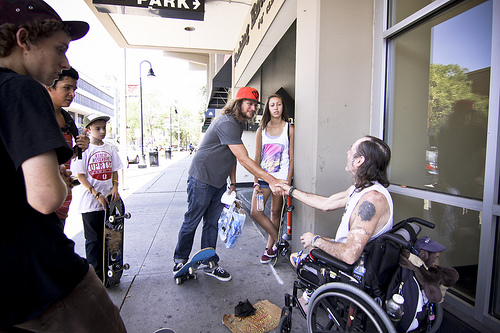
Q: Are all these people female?
A: No, they are both male and female.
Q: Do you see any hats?
A: Yes, there is a hat.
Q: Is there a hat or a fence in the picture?
A: Yes, there is a hat.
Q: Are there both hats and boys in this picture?
A: Yes, there are both a hat and a boy.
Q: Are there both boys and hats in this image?
A: Yes, there are both a hat and a boy.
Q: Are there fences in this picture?
A: No, there are no fences.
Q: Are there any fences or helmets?
A: No, there are no fences or helmets.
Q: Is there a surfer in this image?
A: No, there are no surfers.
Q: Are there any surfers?
A: No, there are no surfers.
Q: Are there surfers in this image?
A: No, there are no surfers.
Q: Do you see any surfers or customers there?
A: No, there are no surfers or customers.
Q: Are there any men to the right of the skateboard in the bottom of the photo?
A: Yes, there is a man to the right of the skateboard.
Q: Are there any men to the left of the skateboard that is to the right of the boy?
A: No, the man is to the right of the skateboard.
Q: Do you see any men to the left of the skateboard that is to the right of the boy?
A: No, the man is to the right of the skateboard.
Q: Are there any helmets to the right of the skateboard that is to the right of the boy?
A: No, there is a man to the right of the skateboard.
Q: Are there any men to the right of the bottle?
A: Yes, there is a man to the right of the bottle.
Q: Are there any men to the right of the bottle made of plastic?
A: Yes, there is a man to the right of the bottle.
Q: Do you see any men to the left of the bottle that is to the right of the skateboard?
A: No, the man is to the right of the bottle.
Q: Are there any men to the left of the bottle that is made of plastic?
A: No, the man is to the right of the bottle.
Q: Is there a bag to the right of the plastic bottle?
A: No, there is a man to the right of the bottle.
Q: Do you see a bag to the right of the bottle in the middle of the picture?
A: No, there is a man to the right of the bottle.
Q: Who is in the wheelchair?
A: The man is in the wheelchair.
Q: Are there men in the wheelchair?
A: Yes, there is a man in the wheelchair.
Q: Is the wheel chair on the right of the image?
A: Yes, the wheel chair is on the right of the image.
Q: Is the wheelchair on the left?
A: No, the wheelchair is on the right of the image.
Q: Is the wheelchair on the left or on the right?
A: The wheelchair is on the right of the image.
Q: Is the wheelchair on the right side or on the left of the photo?
A: The wheelchair is on the right of the image.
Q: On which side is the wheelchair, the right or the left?
A: The wheelchair is on the right of the image.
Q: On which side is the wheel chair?
A: The wheel chair is on the right of the image.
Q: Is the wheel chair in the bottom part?
A: Yes, the wheel chair is in the bottom of the image.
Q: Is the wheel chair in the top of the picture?
A: No, the wheel chair is in the bottom of the image.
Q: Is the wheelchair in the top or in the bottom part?
A: The wheelchair is in the bottom of the image.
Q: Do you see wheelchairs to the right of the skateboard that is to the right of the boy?
A: Yes, there is a wheelchair to the right of the skateboard.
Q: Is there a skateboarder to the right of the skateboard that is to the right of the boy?
A: No, there is a wheelchair to the right of the skateboard.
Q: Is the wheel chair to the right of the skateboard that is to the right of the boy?
A: Yes, the wheel chair is to the right of the skateboard.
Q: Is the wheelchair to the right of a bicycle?
A: No, the wheelchair is to the right of the skateboard.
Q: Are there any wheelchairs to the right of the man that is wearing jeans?
A: Yes, there is a wheelchair to the right of the man.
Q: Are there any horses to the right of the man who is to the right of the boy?
A: No, there is a wheelchair to the right of the man.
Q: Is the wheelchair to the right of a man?
A: Yes, the wheelchair is to the right of a man.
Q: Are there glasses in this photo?
A: No, there are no glasses.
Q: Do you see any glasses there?
A: No, there are no glasses.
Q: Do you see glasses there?
A: No, there are no glasses.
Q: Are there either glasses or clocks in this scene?
A: No, there are no glasses or clocks.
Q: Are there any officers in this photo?
A: No, there are no officers.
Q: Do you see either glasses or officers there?
A: No, there are no officers or glasses.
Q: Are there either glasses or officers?
A: No, there are no officers or glasses.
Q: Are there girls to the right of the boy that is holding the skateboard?
A: Yes, there is a girl to the right of the boy.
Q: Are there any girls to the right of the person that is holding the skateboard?
A: Yes, there is a girl to the right of the boy.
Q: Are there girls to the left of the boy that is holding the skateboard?
A: No, the girl is to the right of the boy.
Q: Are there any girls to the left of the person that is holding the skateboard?
A: No, the girl is to the right of the boy.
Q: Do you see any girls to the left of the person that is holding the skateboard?
A: No, the girl is to the right of the boy.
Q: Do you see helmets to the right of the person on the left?
A: No, there is a girl to the right of the boy.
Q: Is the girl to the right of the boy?
A: Yes, the girl is to the right of the boy.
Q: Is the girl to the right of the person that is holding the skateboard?
A: Yes, the girl is to the right of the boy.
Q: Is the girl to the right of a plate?
A: No, the girl is to the right of the boy.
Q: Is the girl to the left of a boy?
A: No, the girl is to the right of a boy.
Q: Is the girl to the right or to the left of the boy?
A: The girl is to the right of the boy.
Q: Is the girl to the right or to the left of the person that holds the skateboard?
A: The girl is to the right of the boy.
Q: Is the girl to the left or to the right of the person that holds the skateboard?
A: The girl is to the right of the boy.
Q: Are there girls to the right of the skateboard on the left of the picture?
A: Yes, there is a girl to the right of the skateboard.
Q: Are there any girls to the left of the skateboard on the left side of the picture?
A: No, the girl is to the right of the skateboard.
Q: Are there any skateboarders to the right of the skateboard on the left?
A: No, there is a girl to the right of the skateboard.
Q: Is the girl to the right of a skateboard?
A: Yes, the girl is to the right of a skateboard.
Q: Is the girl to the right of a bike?
A: No, the girl is to the right of a skateboard.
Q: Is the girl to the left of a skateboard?
A: No, the girl is to the right of a skateboard.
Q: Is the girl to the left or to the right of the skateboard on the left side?
A: The girl is to the right of the skateboard.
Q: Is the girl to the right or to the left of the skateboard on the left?
A: The girl is to the right of the skateboard.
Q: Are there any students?
A: No, there are no students.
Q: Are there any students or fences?
A: No, there are no students or fences.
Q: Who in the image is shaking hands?
A: The man is shaking hands.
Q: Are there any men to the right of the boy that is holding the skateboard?
A: Yes, there is a man to the right of the boy.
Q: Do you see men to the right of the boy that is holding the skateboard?
A: Yes, there is a man to the right of the boy.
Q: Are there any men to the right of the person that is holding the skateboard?
A: Yes, there is a man to the right of the boy.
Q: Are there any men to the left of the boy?
A: No, the man is to the right of the boy.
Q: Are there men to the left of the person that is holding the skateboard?
A: No, the man is to the right of the boy.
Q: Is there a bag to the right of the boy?
A: No, there is a man to the right of the boy.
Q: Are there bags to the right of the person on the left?
A: No, there is a man to the right of the boy.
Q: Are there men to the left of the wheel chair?
A: Yes, there is a man to the left of the wheel chair.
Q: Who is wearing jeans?
A: The man is wearing jeans.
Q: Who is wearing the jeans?
A: The man is wearing jeans.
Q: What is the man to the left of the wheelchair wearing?
A: The man is wearing jeans.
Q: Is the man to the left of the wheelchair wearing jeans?
A: Yes, the man is wearing jeans.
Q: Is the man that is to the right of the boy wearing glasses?
A: No, the man is wearing jeans.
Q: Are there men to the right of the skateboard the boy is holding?
A: Yes, there is a man to the right of the skateboard.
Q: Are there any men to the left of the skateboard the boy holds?
A: No, the man is to the right of the skateboard.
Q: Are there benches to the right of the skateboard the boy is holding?
A: No, there is a man to the right of the skateboard.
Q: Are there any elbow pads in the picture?
A: No, there are no elbow pads.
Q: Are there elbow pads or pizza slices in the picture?
A: No, there are no elbow pads or pizza slices.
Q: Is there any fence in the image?
A: No, there are no fences.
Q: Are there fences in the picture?
A: No, there are no fences.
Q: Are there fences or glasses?
A: No, there are no fences or glasses.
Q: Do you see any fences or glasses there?
A: No, there are no fences or glasses.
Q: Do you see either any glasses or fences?
A: No, there are no fences or glasses.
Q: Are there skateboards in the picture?
A: Yes, there is a skateboard.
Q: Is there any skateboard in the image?
A: Yes, there is a skateboard.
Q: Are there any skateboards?
A: Yes, there is a skateboard.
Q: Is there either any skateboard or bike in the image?
A: Yes, there is a skateboard.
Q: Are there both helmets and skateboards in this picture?
A: No, there is a skateboard but no helmets.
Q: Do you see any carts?
A: No, there are no carts.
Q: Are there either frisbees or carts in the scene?
A: No, there are no carts or frisbees.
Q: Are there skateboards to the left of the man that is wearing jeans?
A: Yes, there is a skateboard to the left of the man.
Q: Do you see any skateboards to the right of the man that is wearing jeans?
A: No, the skateboard is to the left of the man.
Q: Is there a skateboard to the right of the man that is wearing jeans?
A: No, the skateboard is to the left of the man.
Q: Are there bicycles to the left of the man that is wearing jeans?
A: No, there is a skateboard to the left of the man.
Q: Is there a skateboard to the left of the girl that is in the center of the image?
A: Yes, there is a skateboard to the left of the girl.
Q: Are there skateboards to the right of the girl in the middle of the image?
A: No, the skateboard is to the left of the girl.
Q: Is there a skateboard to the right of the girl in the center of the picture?
A: No, the skateboard is to the left of the girl.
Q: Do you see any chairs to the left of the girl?
A: No, there is a skateboard to the left of the girl.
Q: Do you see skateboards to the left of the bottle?
A: Yes, there is a skateboard to the left of the bottle.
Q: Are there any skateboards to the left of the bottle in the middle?
A: Yes, there is a skateboard to the left of the bottle.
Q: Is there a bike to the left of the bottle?
A: No, there is a skateboard to the left of the bottle.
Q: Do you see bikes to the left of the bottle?
A: No, there is a skateboard to the left of the bottle.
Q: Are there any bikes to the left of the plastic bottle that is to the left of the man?
A: No, there is a skateboard to the left of the bottle.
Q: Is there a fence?
A: No, there are no fences.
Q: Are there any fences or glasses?
A: No, there are no fences or glasses.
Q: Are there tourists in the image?
A: No, there are no tourists.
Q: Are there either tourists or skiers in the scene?
A: No, there are no tourists or skiers.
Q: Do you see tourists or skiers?
A: No, there are no tourists or skiers.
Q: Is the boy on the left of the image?
A: Yes, the boy is on the left of the image.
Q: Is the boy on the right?
A: No, the boy is on the left of the image.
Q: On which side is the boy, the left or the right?
A: The boy is on the left of the image.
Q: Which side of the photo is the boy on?
A: The boy is on the left of the image.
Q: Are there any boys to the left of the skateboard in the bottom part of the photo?
A: Yes, there is a boy to the left of the skateboard.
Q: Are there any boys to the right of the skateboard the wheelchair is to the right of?
A: No, the boy is to the left of the skateboard.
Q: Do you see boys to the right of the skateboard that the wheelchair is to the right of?
A: No, the boy is to the left of the skateboard.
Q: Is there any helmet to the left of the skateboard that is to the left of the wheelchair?
A: No, there is a boy to the left of the skateboard.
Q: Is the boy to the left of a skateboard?
A: Yes, the boy is to the left of a skateboard.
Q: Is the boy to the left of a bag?
A: No, the boy is to the left of a skateboard.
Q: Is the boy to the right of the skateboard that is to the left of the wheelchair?
A: No, the boy is to the left of the skateboard.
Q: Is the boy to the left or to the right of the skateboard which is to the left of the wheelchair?
A: The boy is to the left of the skateboard.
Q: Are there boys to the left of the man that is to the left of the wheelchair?
A: Yes, there is a boy to the left of the man.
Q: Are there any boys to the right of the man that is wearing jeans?
A: No, the boy is to the left of the man.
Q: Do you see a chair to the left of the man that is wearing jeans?
A: No, there is a boy to the left of the man.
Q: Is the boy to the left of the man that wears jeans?
A: Yes, the boy is to the left of the man.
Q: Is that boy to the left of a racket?
A: No, the boy is to the left of the man.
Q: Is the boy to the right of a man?
A: No, the boy is to the left of a man.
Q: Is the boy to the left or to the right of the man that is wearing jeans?
A: The boy is to the left of the man.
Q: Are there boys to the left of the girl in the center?
A: Yes, there is a boy to the left of the girl.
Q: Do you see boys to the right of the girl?
A: No, the boy is to the left of the girl.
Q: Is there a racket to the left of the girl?
A: No, there is a boy to the left of the girl.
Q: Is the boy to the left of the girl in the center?
A: Yes, the boy is to the left of the girl.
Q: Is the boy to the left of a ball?
A: No, the boy is to the left of the girl.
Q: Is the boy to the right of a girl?
A: No, the boy is to the left of a girl.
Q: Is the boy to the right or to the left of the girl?
A: The boy is to the left of the girl.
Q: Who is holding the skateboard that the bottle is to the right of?
A: The boy is holding the skateboard.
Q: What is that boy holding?
A: The boy is holding the skateboard.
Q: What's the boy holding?
A: The boy is holding the skateboard.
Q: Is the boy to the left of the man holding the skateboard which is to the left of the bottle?
A: Yes, the boy is holding the skateboard.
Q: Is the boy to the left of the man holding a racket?
A: No, the boy is holding the skateboard.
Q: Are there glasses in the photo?
A: No, there are no glasses.